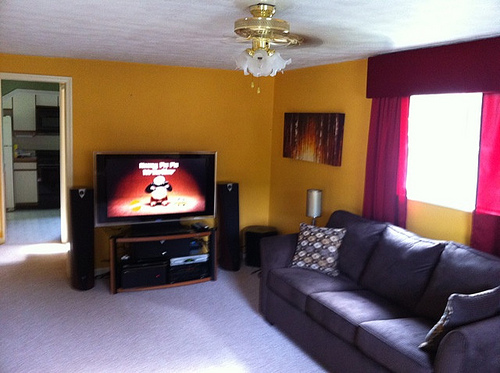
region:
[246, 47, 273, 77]
Most visible largest fan light globe.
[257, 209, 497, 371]
A dark grey couch.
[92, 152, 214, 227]
A flat screen tv.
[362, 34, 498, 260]
Red curtains covering a window.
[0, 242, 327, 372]
White carpet in the living room.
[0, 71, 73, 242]
A white framed doorway.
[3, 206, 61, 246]
A white tiled kitchen floor.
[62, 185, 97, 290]
Tall black speaker to the left of a tv.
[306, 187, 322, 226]
A tall thin silver lamp.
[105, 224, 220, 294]
A brown and black tv stand.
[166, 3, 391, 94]
gold ceiling fan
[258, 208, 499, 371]
purple cloth couch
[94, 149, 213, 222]
flat screen tv with kung fu panda on it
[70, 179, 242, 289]
sound system next to the television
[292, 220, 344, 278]
purple, brown, and white pillow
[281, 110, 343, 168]
painting on the wall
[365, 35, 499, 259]
red curtains on the window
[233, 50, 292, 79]
white floral shaped lights on the fan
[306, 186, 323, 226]
silver floor lamp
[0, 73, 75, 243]
doorway into another room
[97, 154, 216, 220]
the TV is on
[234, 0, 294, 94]
the ceiling fixture is turned off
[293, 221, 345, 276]
pillow has a geometric pattern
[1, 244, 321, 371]
the floor is tidy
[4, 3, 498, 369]
the room is vacant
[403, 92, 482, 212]
sunlight is coming in through the window